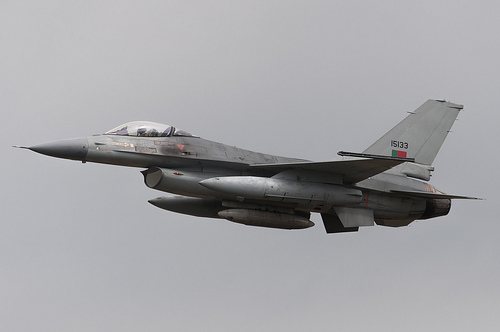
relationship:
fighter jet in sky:
[11, 96, 488, 234] [0, 0, 499, 332]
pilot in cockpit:
[134, 126, 147, 137] [105, 120, 191, 137]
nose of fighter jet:
[9, 134, 88, 161] [11, 96, 488, 234]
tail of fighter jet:
[355, 97, 465, 166] [11, 96, 488, 234]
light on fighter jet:
[171, 170, 181, 177] [11, 96, 488, 234]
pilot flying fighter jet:
[134, 126, 147, 137] [11, 96, 488, 234]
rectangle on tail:
[391, 147, 407, 158] [355, 97, 465, 166]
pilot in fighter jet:
[134, 126, 147, 137] [11, 96, 488, 234]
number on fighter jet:
[389, 138, 394, 149] [11, 96, 488, 234]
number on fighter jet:
[394, 139, 397, 150] [11, 96, 488, 234]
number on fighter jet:
[397, 141, 400, 149] [11, 96, 488, 234]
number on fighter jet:
[400, 140, 404, 150] [11, 96, 488, 234]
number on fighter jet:
[404, 140, 408, 152] [11, 96, 488, 234]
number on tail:
[389, 138, 394, 149] [355, 97, 465, 166]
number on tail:
[394, 139, 397, 150] [355, 97, 465, 166]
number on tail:
[397, 141, 400, 149] [355, 97, 465, 166]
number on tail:
[400, 140, 404, 150] [355, 97, 465, 166]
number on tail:
[404, 140, 408, 152] [355, 97, 465, 166]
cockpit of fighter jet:
[105, 120, 191, 137] [11, 96, 488, 234]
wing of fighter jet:
[251, 155, 408, 183] [11, 96, 488, 234]